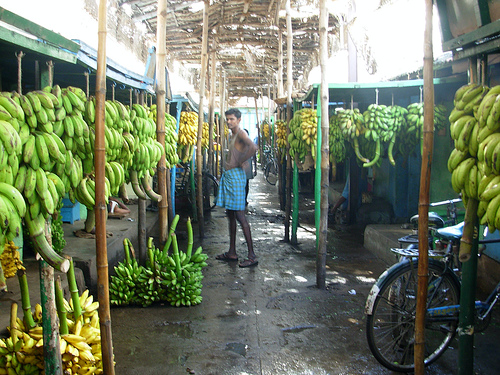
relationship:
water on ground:
[158, 307, 248, 361] [106, 169, 388, 369]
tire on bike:
[341, 242, 457, 362] [317, 181, 482, 353]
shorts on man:
[213, 167, 248, 212] [214, 106, 261, 272]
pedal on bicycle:
[477, 288, 498, 330] [366, 189, 497, 364]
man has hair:
[214, 106, 261, 272] [216, 110, 271, 145]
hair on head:
[216, 110, 271, 145] [223, 108, 244, 130]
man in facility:
[214, 107, 259, 267] [2, 0, 498, 370]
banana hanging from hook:
[0, 84, 499, 375] [369, 89, 382, 107]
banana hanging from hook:
[376, 123, 385, 136] [369, 89, 382, 107]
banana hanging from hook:
[0, 84, 499, 375] [15, 51, 22, 96]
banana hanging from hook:
[0, 84, 499, 375] [43, 59, 53, 84]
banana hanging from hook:
[0, 84, 499, 375] [84, 74, 91, 97]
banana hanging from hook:
[0, 84, 499, 375] [6, 47, 38, 108]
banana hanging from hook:
[0, 84, 499, 375] [45, 55, 54, 89]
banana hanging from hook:
[0, 84, 499, 375] [109, 80, 119, 87]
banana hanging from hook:
[0, 84, 499, 375] [472, 45, 490, 87]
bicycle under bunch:
[364, 198, 500, 374] [445, 83, 499, 238]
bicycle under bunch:
[364, 217, 499, 373] [445, 83, 499, 238]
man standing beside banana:
[214, 107, 259, 267] [0, 84, 499, 375]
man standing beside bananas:
[214, 107, 259, 267] [257, 83, 496, 230]